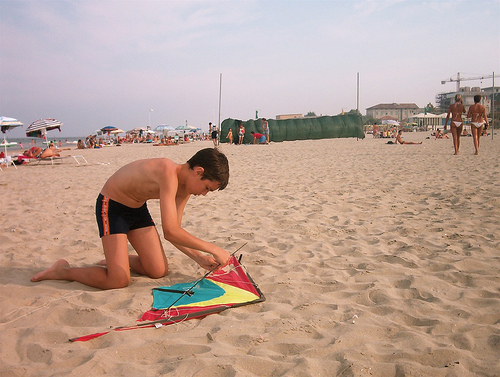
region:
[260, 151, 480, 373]
sandy Beach with foot prints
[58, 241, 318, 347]
A broken yellow, red and blue coloured kite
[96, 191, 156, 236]
Tight nevy blue shorts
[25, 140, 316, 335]
A little boy kneeling on the sand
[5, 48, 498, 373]
A beautiful and busy beach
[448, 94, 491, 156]
Two ladies in white bikini swimsuits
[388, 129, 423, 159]
A man sand bathing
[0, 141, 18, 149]
A white boat on the ocean shore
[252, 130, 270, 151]
A man bending on the ground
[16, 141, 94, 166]
A lady basking in the sun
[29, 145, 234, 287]
Brown haired boy leaning over in the sand.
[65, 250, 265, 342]
Red, yellow and green kite lying in the sand.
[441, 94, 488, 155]
Two women in bikini's walking down the beach.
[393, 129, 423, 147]
Man sitting in the sand with his arms behind him propping him up.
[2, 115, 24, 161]
Half visible mostly white umbrella that sits to the left of another umbrella.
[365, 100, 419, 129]
A large tan colored building in the distance.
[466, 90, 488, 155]
Woman with short brown hair in a bikini to the right of her walking mate.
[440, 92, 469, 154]
Girl in a white bikini with light hair to the left of another girl.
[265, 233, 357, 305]
Divets and footprints in the sand above the kite.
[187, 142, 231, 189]
Brown hair on a boy in the sand.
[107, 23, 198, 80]
sky above the beach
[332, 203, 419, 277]
sand on the ground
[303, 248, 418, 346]
footprints on the beach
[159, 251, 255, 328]
kite on the ground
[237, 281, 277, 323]
top part of kite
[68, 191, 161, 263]
shorts on the kid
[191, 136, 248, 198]
head of the kid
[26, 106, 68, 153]
umbrella in the background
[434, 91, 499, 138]
women on the beach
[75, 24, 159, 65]
clear sky above sand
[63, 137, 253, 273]
this is a boy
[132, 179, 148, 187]
the boy is light skinned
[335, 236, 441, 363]
this is a sandy place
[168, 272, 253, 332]
this is a kite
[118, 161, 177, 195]
the boy is bare chested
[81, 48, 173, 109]
this is the sky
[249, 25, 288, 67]
the sky is blue in color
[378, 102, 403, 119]
this is a building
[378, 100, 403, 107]
this is the roof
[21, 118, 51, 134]
this is an umbrella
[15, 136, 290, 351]
A little boy kneeling on the sand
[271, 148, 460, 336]
Beach sand with lots of footsteps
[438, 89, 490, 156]
Two ladies dressed in white bikini swimsuits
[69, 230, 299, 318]
A blue,red and yellow coloured kite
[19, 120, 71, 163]
A lady basking on the sun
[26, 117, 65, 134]
A white checked Grey umbrella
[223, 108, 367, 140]
A green rectangular tent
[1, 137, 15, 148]
A white boat in the ocean shore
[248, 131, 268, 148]
Fully dressed man in the beach